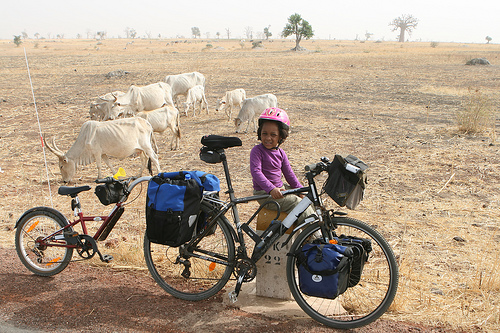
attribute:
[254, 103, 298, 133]
helmet — pink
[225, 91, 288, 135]
cow — white, grazing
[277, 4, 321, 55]
tree — tall, distant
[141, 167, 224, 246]
storage bag — blue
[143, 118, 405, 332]
bicycle — red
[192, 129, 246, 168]
seat — black, raised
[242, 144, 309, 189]
shirt — purple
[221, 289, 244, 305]
petal — metal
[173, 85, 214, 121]
goat — white